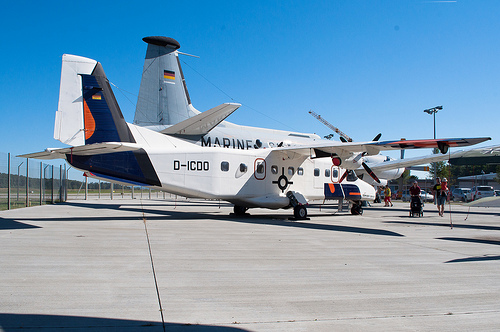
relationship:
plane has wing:
[15, 52, 492, 221] [159, 99, 241, 140]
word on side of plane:
[199, 130, 259, 152] [62, 222, 229, 265]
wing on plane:
[269, 127, 483, 175] [93, 76, 490, 233]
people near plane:
[407, 175, 422, 215] [15, 52, 492, 221]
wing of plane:
[271, 135, 492, 152] [15, 52, 492, 221]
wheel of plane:
[255, 188, 370, 227] [118, 120, 448, 250]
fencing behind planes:
[54, 183, 161, 197] [14, 35, 492, 219]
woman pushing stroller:
[407, 176, 427, 219] [406, 174, 426, 221]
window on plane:
[256, 157, 264, 175] [55, 52, 485, 210]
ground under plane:
[11, 214, 496, 329] [15, 52, 492, 221]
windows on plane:
[218, 158, 339, 178] [15, 52, 492, 221]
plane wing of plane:
[329, 88, 495, 258] [55, 52, 485, 210]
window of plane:
[254, 159, 264, 174] [15, 52, 492, 221]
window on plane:
[218, 158, 230, 173] [15, 52, 492, 221]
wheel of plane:
[293, 197, 308, 226] [57, 33, 489, 250]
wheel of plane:
[346, 197, 368, 214] [57, 33, 489, 250]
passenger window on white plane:
[220, 159, 229, 172] [14, 35, 492, 220]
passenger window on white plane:
[239, 162, 248, 173] [14, 35, 492, 220]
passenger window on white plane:
[270, 164, 278, 174] [14, 35, 492, 220]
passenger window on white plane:
[285, 165, 296, 176] [14, 35, 492, 220]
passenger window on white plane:
[315, 165, 319, 175] [14, 35, 492, 220]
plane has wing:
[15, 52, 492, 221] [55, 49, 134, 147]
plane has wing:
[15, 52, 492, 221] [15, 139, 141, 166]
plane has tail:
[37, 41, 419, 210] [34, 38, 123, 172]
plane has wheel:
[15, 52, 492, 221] [230, 200, 248, 216]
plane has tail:
[15, 52, 492, 221] [14, 53, 142, 173]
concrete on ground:
[12, 210, 497, 322] [2, 197, 494, 330]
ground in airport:
[2, 197, 494, 330] [0, 143, 499, 329]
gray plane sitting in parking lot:
[130, 36, 499, 187] [1, 197, 499, 330]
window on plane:
[295, 166, 306, 176] [15, 52, 492, 221]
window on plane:
[319, 160, 346, 187] [33, 43, 438, 258]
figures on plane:
[172, 158, 210, 172] [15, 52, 492, 221]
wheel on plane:
[290, 200, 309, 221] [15, 52, 492, 221]